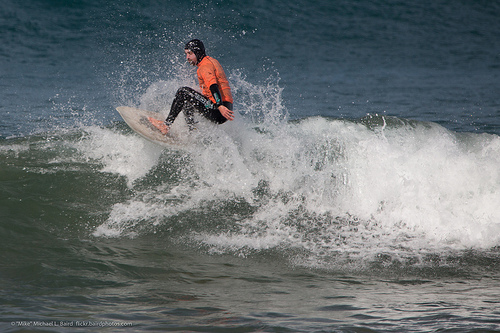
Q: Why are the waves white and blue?
A: The waves are white when crashing onto the blue of the water.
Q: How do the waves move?
A: The waves move up and down in a circular motion.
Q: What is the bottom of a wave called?
A: The bottom part of a wave is the trough.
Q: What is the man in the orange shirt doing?
A: The man is surfing.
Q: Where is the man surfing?
A: The man is surfing the waves of the ocean.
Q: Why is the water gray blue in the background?
A: The gray blue water is deeper water.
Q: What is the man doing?
A: Surfing.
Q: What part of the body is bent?
A: Legs.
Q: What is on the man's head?
A: Hood.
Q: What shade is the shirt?
A: Orange.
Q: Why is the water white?
A: Crashing waves.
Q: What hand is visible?
A: Right hand.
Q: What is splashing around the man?
A: Water.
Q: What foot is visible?
A: Left foot.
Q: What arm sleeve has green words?
A: Left arm sleeve.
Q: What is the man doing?
A: Standing on a surfboard.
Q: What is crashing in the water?
A: Waves.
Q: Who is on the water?
A: A surfer.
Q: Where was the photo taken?
A: In the ocean.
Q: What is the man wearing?
A: Wet suit.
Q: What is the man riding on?
A: Surfboard.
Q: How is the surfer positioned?
A: Crouched.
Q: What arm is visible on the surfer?
A: Left arm.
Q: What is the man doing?
A: Surfing.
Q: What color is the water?
A: Blue.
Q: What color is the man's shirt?
A: Orange.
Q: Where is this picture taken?
A: In the ocean.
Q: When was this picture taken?
A: Daytime.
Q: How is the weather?
A: Clear.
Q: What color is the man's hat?
A: Black.